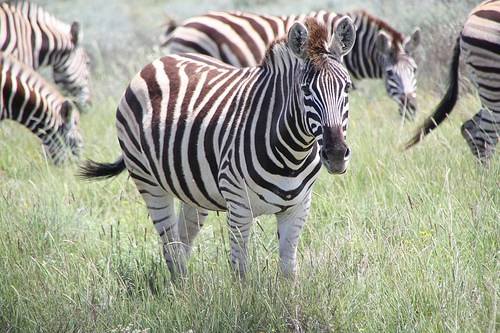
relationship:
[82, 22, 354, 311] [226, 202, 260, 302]
zebra has leg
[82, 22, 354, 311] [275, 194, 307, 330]
zebra has leg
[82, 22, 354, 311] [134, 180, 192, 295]
zebra has leg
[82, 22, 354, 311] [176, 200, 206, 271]
zebra has leg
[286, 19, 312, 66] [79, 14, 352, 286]
ear of a zebra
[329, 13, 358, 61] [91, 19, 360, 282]
ear of a zebra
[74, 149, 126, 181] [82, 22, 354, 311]
tail of a zebra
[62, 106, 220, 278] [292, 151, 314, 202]
black and white striped zebra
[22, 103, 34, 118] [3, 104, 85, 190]
black and white striped zebra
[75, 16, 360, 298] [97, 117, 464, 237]
zebra zebras are black and white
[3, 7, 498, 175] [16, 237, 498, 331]
zebras in field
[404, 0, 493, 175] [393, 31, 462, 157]
zebra has tail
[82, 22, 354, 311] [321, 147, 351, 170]
zebra has nose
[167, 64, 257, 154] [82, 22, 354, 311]
stripes on zebra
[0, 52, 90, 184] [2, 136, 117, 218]
zebra eating grass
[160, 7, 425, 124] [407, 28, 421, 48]
zebra has ear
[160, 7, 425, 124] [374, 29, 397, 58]
zebra has ear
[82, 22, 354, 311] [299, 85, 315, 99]
zebra has eye